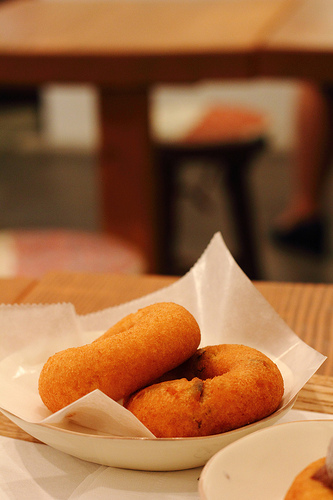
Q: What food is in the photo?
A: Donuts.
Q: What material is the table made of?
A: Wood.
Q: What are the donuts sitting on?
A: White paper.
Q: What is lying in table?
A: Cake.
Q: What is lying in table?
A: Paper.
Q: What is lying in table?
A: Saucer.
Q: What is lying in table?
A: Donuts.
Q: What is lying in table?
A: Donus.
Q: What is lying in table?
A: Donuts.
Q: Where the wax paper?
A: Donuts.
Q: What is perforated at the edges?
A: Wax paper.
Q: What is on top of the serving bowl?
A: Wax paper.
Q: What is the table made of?
A: Wood.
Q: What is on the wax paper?
A: Cake donuts.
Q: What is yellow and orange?
A: Cake donuts.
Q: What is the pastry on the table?
A: Donut.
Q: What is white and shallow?
A: The bowls.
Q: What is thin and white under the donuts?
A: Paper.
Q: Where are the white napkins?
A: Under the bowls.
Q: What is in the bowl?
A: Two donuts.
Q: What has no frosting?
A: The donut.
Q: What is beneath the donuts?
A: White paper.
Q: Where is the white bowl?
A: On the table.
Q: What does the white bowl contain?
A: Food.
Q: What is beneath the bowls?
A: A table.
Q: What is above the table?
A: Two donuts.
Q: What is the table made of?
A: Wood.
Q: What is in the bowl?
A: A white sheet.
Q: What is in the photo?
A: Doughnuts.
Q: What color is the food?
A: Brown.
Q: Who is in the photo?
A: No one.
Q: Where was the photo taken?
A: At a doughnut shop.